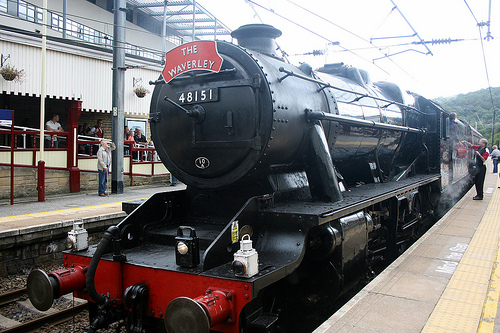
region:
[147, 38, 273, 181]
The front of the train is red, white and black.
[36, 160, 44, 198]
The pole is red.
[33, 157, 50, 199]
The pole is made of steel.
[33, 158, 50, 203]
The pole is short.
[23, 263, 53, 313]
The train bumper is round.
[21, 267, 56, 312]
The train bumper is made of steel.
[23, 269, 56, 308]
The train bumper is dark in color.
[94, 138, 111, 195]
The man is wearing blue jeans.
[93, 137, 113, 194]
The man is wearing a jacket.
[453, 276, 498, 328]
The pavement has a yellow stripe.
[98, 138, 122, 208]
A person standing on the truck side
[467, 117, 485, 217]
A person standing on the truck side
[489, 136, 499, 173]
A person standing on the truck side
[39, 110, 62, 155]
A person seated on the truck side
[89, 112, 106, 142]
A person seated on the truck side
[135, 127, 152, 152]
A person seated on the truck side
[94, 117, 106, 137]
A person seated on the truck side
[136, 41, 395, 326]
A black train on the trucks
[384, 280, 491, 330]
A smooth tile pavement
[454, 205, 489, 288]
A smooth tile pavement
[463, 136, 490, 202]
the man next to the train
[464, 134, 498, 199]
the people on the train patform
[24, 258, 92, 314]
the bumper on the front of the train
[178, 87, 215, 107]
the number on the frontof the train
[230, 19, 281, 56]
the chimney stack on the train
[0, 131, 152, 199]
the ramp on the platform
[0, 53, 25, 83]
the plant hanging on the wall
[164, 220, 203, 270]
the light on the front of the train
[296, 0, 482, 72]
the wires hanging overhead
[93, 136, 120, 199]
the man holding a cane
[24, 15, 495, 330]
The train is long.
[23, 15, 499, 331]
The train is black.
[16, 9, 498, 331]
Th train is on the track.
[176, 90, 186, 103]
The number is white.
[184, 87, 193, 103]
The number is white.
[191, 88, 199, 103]
The number is white.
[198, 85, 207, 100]
The number is white.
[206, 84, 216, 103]
The number is white.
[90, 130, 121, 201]
The man is holding a cane.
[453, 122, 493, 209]
The man is standing on the platform next to the train.